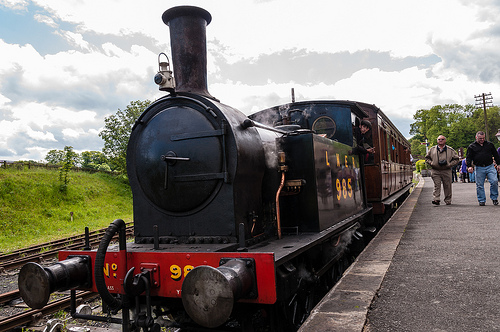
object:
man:
[424, 135, 460, 207]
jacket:
[425, 145, 460, 170]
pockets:
[438, 160, 447, 167]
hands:
[442, 164, 452, 170]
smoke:
[249, 94, 318, 169]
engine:
[18, 5, 374, 332]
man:
[355, 120, 375, 155]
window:
[355, 116, 360, 155]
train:
[19, 5, 417, 332]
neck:
[438, 144, 445, 147]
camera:
[437, 145, 448, 167]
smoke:
[320, 228, 356, 264]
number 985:
[336, 178, 353, 201]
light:
[392, 145, 395, 150]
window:
[392, 137, 393, 162]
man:
[466, 131, 500, 206]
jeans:
[475, 165, 499, 202]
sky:
[0, 0, 498, 166]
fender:
[58, 250, 277, 304]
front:
[126, 92, 238, 236]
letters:
[326, 151, 356, 168]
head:
[360, 120, 372, 135]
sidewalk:
[297, 173, 499, 332]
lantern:
[153, 52, 175, 91]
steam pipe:
[275, 150, 288, 240]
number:
[170, 264, 194, 281]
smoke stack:
[161, 5, 213, 92]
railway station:
[0, 0, 497, 332]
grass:
[0, 160, 133, 258]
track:
[0, 220, 293, 332]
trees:
[418, 160, 430, 174]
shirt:
[466, 141, 500, 168]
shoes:
[431, 200, 440, 205]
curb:
[299, 176, 500, 332]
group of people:
[461, 159, 470, 183]